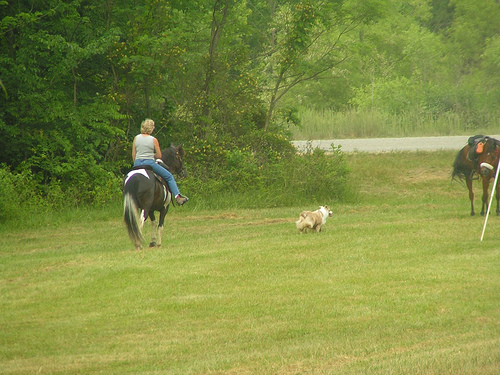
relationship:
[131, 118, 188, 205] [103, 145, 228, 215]
person riding horse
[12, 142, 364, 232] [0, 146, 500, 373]
vegatation in field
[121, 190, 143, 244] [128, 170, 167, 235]
tail of horse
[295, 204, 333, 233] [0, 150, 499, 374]
dog on grass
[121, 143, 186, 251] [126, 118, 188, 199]
horse under person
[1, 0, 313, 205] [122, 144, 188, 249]
leaves next to horse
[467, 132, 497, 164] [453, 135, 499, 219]
saddle atop horse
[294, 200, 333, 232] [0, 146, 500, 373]
dog in a field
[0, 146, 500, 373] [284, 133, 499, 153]
field next to road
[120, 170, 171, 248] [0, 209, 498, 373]
horse on ground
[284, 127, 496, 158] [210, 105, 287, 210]
road near bushes